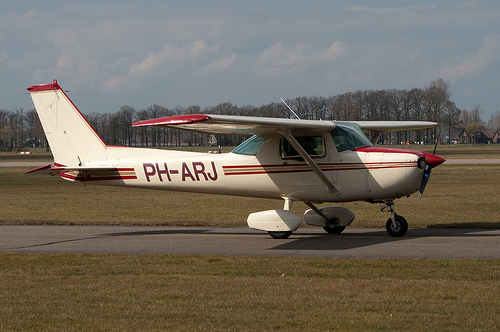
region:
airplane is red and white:
[22, 83, 446, 241]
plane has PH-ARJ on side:
[141, 158, 219, 184]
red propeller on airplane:
[415, 137, 447, 197]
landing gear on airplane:
[235, 192, 411, 239]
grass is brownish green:
[0, 142, 498, 330]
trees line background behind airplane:
[2, 78, 498, 154]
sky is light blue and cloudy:
[1, 0, 498, 144]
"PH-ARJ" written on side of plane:
[139, 158, 221, 186]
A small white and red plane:
[23, 76, 449, 242]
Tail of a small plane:
[24, 76, 108, 151]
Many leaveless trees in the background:
[1, 77, 499, 154]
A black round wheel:
[383, 211, 412, 241]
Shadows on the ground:
[9, 218, 498, 253]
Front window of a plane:
[329, 117, 374, 155]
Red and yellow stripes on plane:
[48, 158, 425, 184]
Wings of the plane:
[129, 108, 443, 139]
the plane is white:
[50, 84, 467, 223]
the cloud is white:
[263, 18, 365, 75]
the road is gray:
[206, 221, 404, 281]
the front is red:
[420, 142, 445, 174]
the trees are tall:
[191, 89, 437, 149]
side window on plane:
[277, 125, 329, 163]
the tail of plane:
[37, 79, 88, 179]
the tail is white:
[28, 76, 114, 168]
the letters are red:
[134, 157, 224, 182]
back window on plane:
[240, 136, 276, 176]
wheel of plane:
[266, 219, 298, 240]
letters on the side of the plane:
[148, 160, 211, 185]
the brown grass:
[71, 282, 147, 327]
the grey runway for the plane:
[84, 230, 124, 247]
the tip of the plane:
[417, 153, 441, 176]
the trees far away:
[110, 106, 126, 124]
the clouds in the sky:
[113, 65, 135, 76]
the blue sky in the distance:
[365, 58, 397, 80]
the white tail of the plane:
[36, 91, 95, 148]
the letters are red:
[141, 151, 228, 193]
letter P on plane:
[126, 157, 161, 189]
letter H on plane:
[151, 162, 178, 192]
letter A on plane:
[176, 157, 193, 187]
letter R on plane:
[191, 164, 213, 181]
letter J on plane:
[207, 157, 222, 187]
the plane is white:
[24, 69, 433, 271]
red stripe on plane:
[217, 142, 420, 187]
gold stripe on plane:
[221, 161, 423, 176]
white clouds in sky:
[164, 14, 374, 76]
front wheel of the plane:
[378, 208, 420, 238]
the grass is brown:
[223, 281, 295, 321]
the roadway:
[145, 235, 180, 254]